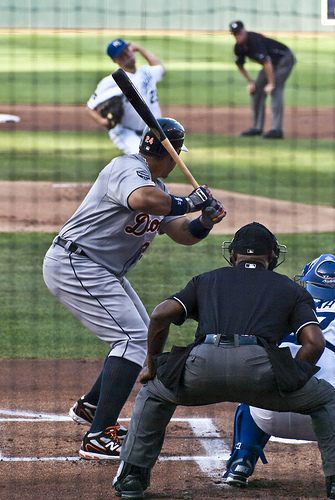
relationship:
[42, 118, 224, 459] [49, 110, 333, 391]
baseball player at homebase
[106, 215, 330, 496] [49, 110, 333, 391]
guy at homebase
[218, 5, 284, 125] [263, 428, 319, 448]
umpire crouched behind homeplate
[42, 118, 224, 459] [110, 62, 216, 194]
baseball player holding bat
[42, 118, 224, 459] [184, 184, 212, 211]
baseball player wearing glove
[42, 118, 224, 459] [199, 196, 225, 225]
baseball player wearing glove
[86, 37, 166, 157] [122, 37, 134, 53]
baseball player pitching ball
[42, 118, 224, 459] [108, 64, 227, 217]
baseball player holding bat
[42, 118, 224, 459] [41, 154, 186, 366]
baseball player wearing grey uniform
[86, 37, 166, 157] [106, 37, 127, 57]
baseball player wearing a hat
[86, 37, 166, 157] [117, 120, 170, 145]
baseball player wearing belt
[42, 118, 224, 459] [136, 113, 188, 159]
baseball player wearing blue helmet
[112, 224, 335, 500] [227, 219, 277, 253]
guy wearing hat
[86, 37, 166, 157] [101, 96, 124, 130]
baseball player holding glove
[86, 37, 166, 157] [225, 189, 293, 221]
baseball player standing on mound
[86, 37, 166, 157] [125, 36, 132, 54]
baseball player throwing ball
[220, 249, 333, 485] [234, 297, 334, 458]
catcher in blue/white uniform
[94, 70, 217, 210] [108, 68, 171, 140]
bat with end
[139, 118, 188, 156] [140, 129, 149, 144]
blue helmet with number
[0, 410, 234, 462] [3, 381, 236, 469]
lines marking box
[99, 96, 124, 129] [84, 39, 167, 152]
glove worn by pitcher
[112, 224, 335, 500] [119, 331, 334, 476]
guy wearing pants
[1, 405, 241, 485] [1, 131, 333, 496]
lines on ground